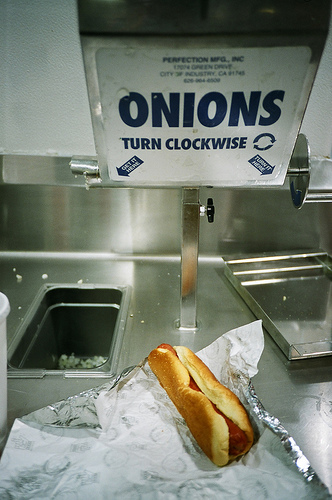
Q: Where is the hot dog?
A: In a bun.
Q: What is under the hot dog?
A: Wrapping paper.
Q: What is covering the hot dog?
A: A bun.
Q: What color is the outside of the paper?
A: Silver.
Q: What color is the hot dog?
A: Red.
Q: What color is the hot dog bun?
A: Brown.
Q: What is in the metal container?
A: Onions.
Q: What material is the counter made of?
A: Stainless steel.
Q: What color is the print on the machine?
A: Blue.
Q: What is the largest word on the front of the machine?
A: Onions.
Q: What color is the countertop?
A: Silver.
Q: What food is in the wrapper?
A: A hotdog.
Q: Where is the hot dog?
A: In the bun.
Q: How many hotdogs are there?
A: 1.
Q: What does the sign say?
A: Onions turn clockwise.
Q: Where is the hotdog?
A: On the foil.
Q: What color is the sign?
A: White and blue.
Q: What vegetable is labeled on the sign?
A: Onions.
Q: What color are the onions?
A: White.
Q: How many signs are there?
A: 1.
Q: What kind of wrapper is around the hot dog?
A: Foil.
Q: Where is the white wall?
A: Behind the onion dispenser.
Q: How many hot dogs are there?
A: One.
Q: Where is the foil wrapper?
A: Under the hot dog.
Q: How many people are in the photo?
A: Zero.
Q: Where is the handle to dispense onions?
A: On the righthand side.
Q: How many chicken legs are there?
A: Zero.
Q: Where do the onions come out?
A: On the left hand side of the dispenser.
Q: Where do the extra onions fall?
A: Into the container on the left.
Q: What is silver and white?
A: Aluminum foil.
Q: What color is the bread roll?
A: Brown.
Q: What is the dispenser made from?
A: Stainless steel.